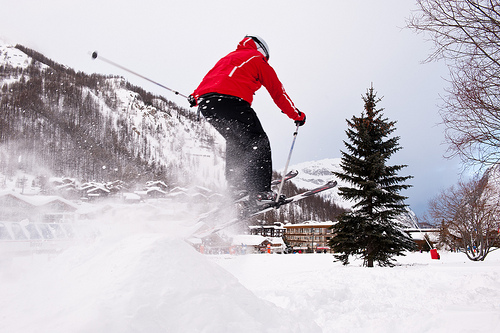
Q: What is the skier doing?
A: Going off a jump.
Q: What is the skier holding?
A: Poles.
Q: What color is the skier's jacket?
A: Red.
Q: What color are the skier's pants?
A: Black.